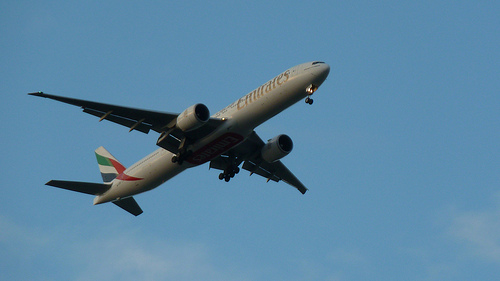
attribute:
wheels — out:
[296, 76, 320, 108]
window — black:
[310, 59, 325, 66]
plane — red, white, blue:
[23, 59, 332, 217]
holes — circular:
[168, 101, 294, 158]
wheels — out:
[214, 162, 239, 184]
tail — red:
[32, 170, 152, 223]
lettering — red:
[234, 67, 296, 112]